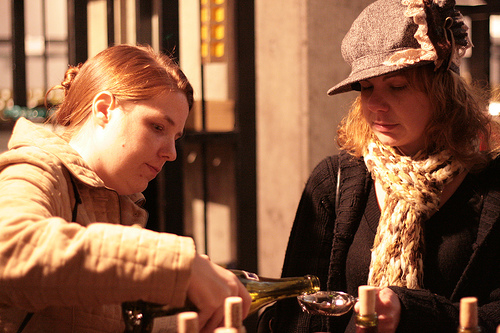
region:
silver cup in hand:
[300, 291, 353, 314]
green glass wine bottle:
[140, 270, 317, 320]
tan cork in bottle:
[358, 286, 376, 312]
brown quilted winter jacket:
[3, 118, 194, 331]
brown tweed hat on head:
[328, 3, 463, 86]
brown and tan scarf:
[364, 140, 452, 300]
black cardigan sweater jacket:
[286, 158, 496, 330]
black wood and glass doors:
[13, 2, 256, 269]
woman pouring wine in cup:
[8, 47, 248, 330]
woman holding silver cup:
[292, 3, 499, 331]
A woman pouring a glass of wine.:
[1, 46, 353, 329]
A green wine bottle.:
[120, 270, 321, 330]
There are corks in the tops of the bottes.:
[165, 285, 491, 332]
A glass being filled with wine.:
[293, 287, 353, 322]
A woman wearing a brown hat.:
[325, 0, 455, 95]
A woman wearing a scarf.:
[356, 136, 466, 286]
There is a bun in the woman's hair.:
[55, 63, 82, 85]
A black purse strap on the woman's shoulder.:
[325, 150, 345, 271]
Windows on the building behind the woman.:
[15, 45, 250, 285]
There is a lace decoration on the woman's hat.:
[406, 0, 471, 55]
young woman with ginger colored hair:
[6, 32, 216, 199]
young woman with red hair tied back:
[23, 34, 214, 198]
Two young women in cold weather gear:
[12, 3, 479, 320]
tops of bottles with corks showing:
[156, 282, 486, 332]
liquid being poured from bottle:
[167, 256, 351, 317]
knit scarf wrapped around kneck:
[357, 119, 493, 234]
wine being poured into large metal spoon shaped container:
[235, 268, 372, 323]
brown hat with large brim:
[316, 1, 478, 95]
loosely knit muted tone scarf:
[365, 136, 481, 304]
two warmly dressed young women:
[0, 4, 488, 326]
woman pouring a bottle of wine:
[31, 50, 326, 323]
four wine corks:
[177, 287, 480, 326]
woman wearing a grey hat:
[341, 9, 476, 108]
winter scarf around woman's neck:
[357, 118, 482, 281]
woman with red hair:
[17, 28, 202, 192]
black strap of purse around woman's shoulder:
[20, 141, 85, 331]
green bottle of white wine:
[122, 255, 331, 326]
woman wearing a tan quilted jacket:
[22, 123, 119, 310]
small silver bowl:
[300, 270, 360, 317]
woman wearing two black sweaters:
[295, 145, 498, 316]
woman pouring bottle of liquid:
[5, 42, 252, 332]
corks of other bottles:
[167, 287, 480, 332]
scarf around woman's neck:
[353, 133, 482, 287]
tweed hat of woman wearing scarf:
[332, 3, 461, 98]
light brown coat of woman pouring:
[14, 132, 202, 325]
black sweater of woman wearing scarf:
[279, 156, 499, 317]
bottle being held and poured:
[125, 273, 321, 332]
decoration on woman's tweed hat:
[406, 9, 475, 66]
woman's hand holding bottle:
[177, 249, 262, 331]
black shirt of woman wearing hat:
[348, 174, 498, 315]